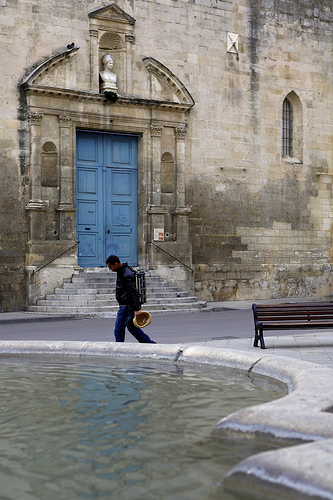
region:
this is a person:
[93, 236, 173, 346]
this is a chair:
[237, 287, 332, 355]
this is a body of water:
[16, 358, 177, 496]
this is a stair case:
[55, 268, 101, 334]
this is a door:
[75, 129, 145, 282]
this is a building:
[12, 2, 244, 336]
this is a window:
[257, 58, 323, 204]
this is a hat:
[128, 308, 160, 334]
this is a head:
[103, 251, 131, 280]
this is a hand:
[123, 267, 149, 322]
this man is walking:
[84, 251, 174, 362]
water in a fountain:
[4, 350, 300, 497]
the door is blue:
[61, 122, 155, 267]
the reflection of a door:
[69, 360, 162, 477]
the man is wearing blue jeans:
[91, 237, 168, 348]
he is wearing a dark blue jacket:
[97, 239, 149, 309]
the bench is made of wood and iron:
[236, 286, 331, 347]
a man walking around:
[101, 245, 165, 344]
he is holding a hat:
[107, 251, 149, 337]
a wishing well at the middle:
[4, 329, 326, 498]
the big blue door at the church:
[71, 118, 157, 266]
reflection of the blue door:
[69, 363, 163, 485]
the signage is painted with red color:
[149, 223, 169, 249]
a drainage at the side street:
[209, 331, 247, 346]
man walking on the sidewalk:
[101, 251, 169, 350]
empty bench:
[244, 301, 331, 350]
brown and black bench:
[248, 300, 332, 348]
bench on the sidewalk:
[241, 297, 331, 359]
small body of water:
[0, 350, 315, 498]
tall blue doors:
[70, 127, 151, 270]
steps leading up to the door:
[26, 248, 214, 316]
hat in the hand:
[126, 306, 159, 332]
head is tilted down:
[104, 251, 121, 277]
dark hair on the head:
[104, 254, 122, 261]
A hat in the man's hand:
[133, 309, 152, 327]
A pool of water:
[0, 345, 273, 492]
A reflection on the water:
[82, 353, 160, 478]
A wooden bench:
[247, 300, 332, 345]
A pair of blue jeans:
[112, 304, 152, 343]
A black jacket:
[115, 265, 143, 310]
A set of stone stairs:
[37, 263, 212, 315]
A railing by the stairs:
[148, 237, 194, 274]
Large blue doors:
[73, 132, 142, 269]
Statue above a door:
[98, 53, 123, 99]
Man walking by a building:
[103, 253, 158, 349]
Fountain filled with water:
[6, 346, 307, 493]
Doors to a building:
[76, 130, 144, 263]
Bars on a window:
[282, 103, 293, 151]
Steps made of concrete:
[75, 272, 185, 311]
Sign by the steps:
[152, 227, 167, 243]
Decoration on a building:
[92, 28, 135, 96]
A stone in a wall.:
[239, 254, 255, 263]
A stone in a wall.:
[241, 235, 257, 241]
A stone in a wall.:
[256, 235, 271, 243]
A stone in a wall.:
[264, 227, 282, 236]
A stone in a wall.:
[270, 223, 288, 230]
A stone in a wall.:
[281, 228, 296, 239]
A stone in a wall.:
[290, 254, 305, 259]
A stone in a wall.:
[279, 254, 291, 264]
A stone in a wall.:
[266, 256, 280, 264]